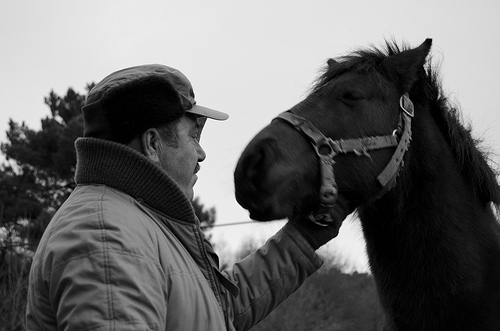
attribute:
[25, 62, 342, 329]
man — wearing, petting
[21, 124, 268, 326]
man/heavy jacket — wearing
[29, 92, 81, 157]
tall tree — behind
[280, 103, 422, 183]
balck strap — black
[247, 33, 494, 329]
horse — brown